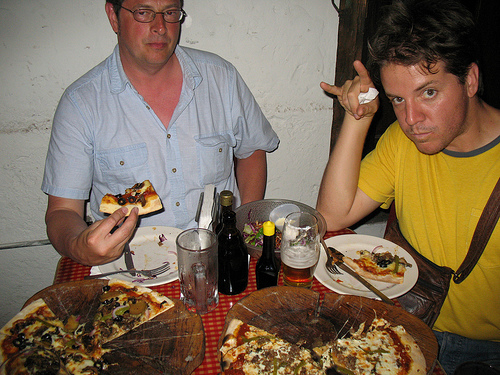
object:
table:
[52, 228, 442, 374]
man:
[39, 0, 281, 268]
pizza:
[96, 180, 164, 216]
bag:
[371, 177, 498, 332]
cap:
[259, 220, 276, 237]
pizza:
[86, 277, 178, 348]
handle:
[190, 262, 209, 310]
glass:
[173, 227, 221, 316]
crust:
[96, 195, 166, 217]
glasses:
[112, 2, 188, 25]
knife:
[122, 244, 136, 277]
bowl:
[226, 198, 327, 264]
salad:
[240, 219, 311, 254]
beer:
[213, 190, 250, 296]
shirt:
[349, 118, 499, 342]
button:
[169, 167, 178, 174]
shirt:
[38, 43, 283, 234]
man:
[313, 0, 500, 374]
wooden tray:
[0, 275, 206, 374]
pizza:
[320, 324, 430, 374]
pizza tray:
[216, 283, 441, 374]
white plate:
[87, 224, 195, 287]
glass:
[277, 210, 322, 291]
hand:
[317, 59, 379, 121]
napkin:
[357, 87, 381, 105]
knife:
[335, 261, 391, 303]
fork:
[318, 235, 341, 274]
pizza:
[335, 248, 411, 284]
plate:
[311, 233, 419, 301]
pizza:
[0, 297, 100, 374]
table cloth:
[50, 226, 448, 374]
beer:
[279, 244, 317, 287]